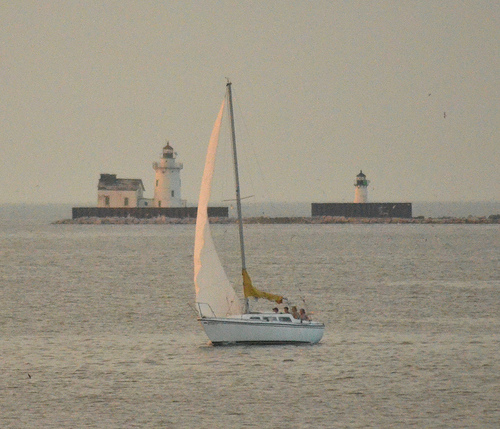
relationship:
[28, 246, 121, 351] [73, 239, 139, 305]
ripple in water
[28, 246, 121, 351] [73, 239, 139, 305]
ripple i water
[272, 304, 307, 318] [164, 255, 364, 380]
people i boat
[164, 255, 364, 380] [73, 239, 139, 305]
boat in water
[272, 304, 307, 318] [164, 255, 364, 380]
people in boat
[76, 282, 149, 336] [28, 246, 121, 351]
sea has ripple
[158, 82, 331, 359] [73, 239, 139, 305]
yacht in water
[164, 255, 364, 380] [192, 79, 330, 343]
people on boat